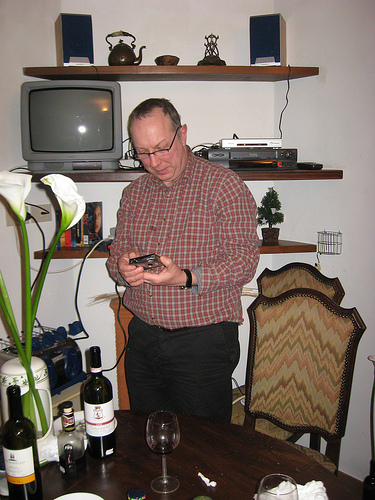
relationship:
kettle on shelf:
[103, 27, 148, 67] [20, 61, 322, 84]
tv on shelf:
[20, 80, 121, 172] [23, 152, 348, 186]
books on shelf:
[55, 200, 102, 248] [22, 63, 319, 82]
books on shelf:
[55, 200, 102, 248] [31, 237, 317, 260]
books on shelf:
[55, 200, 102, 248] [13, 162, 343, 181]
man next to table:
[105, 97, 258, 419] [0, 409, 374, 497]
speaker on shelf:
[248, 12, 287, 68] [23, 64, 319, 84]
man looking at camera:
[105, 97, 258, 419] [129, 251, 162, 274]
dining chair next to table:
[246, 293, 361, 467] [0, 409, 374, 497]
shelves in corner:
[11, 63, 344, 259] [46, 0, 287, 15]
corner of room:
[46, 0, 287, 15] [5, 2, 369, 497]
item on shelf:
[247, 182, 290, 243] [255, 242, 322, 252]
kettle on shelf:
[106, 31, 147, 67] [22, 63, 319, 82]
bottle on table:
[81, 345, 115, 459] [0, 409, 374, 497]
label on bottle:
[3, 444, 37, 487] [2, 384, 39, 498]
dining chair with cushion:
[243, 288, 367, 468] [249, 296, 349, 440]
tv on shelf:
[26, 82, 121, 173] [4, 165, 142, 181]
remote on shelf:
[298, 159, 324, 172] [32, 160, 347, 185]